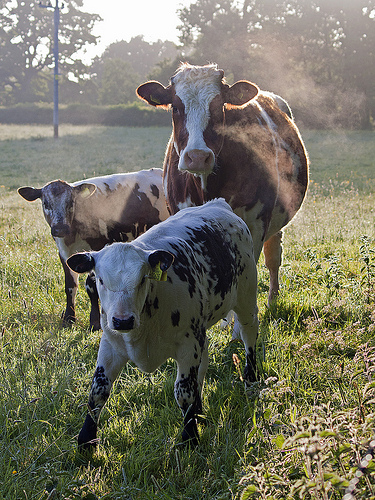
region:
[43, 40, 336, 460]
group of three cows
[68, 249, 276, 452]
black and white calf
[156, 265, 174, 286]
yellow tag in calf ear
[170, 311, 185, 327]
black spot on calf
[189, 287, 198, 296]
black spot on calf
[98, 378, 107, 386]
black spot on calf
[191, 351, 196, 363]
black spot on calf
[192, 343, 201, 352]
black spot on calf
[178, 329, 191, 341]
black spot on calf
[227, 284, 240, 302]
black spot on calf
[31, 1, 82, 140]
a pole in the middle of a field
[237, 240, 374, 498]
a group of wildflowers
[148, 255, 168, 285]
a tag in the cow's ear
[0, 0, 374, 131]
trees on the edge of the field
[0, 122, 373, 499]
a field of grass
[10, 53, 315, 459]
a group of three cows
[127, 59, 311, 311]
a large brown and white cow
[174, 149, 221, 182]
grass in the cow's mouth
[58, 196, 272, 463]
a small black and white cow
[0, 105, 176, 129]
tall grass at the edge of the field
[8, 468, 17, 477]
tiny yellow flower in the grass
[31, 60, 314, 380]
three cows in a pasture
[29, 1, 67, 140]
tall power utility pole in a pasture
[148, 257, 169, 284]
yellow ear ID tag on a white cow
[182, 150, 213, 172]
pink cow nose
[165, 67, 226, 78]
adult cow's horn nubs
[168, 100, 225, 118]
two eyes on an adult cow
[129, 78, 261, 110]
two furry ears on an adult cow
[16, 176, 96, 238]
black speckled face of a black and white cow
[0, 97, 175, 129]
green hedge behind the utility pole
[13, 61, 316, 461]
a mother cow with two calves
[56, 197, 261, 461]
the calf is black and white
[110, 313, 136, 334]
the baby calf nose is black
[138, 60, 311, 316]
the mother calf is brown and white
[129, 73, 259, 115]
the cow has brown ears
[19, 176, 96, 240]
the baby calf has a brown and white face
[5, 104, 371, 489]
the cows are in a pasture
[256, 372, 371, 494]
flowers are on the weeds in the field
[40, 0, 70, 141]
a pole is in the field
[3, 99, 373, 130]
a hedge surrounds the field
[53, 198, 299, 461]
white cow with black speckles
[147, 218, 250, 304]
black speckles on white cow's side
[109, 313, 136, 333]
black nose of white cow with speckles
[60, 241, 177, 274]
black ears of white cow with speckles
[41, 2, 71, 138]
light pole in distance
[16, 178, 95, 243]
white and brown speckles cow's face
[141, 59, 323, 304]
large cow with brown and white markings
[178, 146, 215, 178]
pink nose of brown and white cow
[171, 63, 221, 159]
white marking on brown and white cow's face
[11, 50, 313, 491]
three cows in grassy field